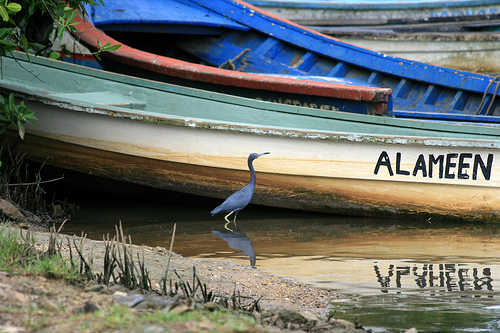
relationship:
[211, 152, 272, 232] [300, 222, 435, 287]
bird standing on water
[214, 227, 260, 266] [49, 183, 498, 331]
reflection in water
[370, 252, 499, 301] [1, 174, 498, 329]
reflection in water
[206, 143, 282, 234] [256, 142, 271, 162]
bird with beak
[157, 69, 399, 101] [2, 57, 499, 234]
edge of boat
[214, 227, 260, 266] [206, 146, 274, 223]
reflection of bird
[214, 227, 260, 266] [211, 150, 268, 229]
reflection of bird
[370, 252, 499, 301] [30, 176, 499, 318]
reflection of water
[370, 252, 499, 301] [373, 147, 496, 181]
reflection in letters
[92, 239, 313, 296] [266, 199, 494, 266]
dirt near water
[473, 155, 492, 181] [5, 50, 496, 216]
letter on boat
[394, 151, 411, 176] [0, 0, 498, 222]
l on boat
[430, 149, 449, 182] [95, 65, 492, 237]
black m on boat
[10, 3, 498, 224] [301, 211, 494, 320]
boats in water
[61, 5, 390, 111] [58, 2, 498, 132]
trim on boat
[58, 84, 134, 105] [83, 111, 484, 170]
seat inside boat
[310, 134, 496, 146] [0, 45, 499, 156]
paint on trim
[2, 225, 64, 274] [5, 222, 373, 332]
grass on shore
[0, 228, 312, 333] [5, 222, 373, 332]
dirt on shore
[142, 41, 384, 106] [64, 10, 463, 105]
paint on side of canoe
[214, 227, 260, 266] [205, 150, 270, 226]
reflection of bird